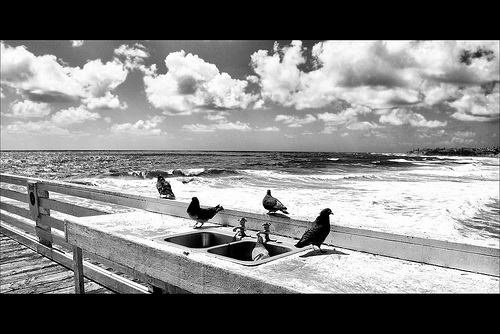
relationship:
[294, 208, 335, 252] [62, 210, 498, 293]
bird on counter area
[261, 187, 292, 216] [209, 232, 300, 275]
bird in sink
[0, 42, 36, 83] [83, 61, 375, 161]
clouds against sky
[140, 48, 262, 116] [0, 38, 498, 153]
cloud against sky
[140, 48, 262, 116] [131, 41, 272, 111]
cloud against sky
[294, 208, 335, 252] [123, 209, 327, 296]
bird on table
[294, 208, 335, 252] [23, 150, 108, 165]
bird outside by water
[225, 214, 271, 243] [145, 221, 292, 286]
faucet on double sink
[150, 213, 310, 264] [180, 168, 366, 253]
double sink near birds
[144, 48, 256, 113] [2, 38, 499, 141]
cloud in sky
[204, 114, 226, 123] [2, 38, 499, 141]
cloud in sky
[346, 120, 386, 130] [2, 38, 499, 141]
cloud in sky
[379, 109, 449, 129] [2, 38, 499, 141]
cloud in sky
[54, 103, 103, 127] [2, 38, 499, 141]
cloud in sky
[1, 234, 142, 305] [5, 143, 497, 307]
deck outside by water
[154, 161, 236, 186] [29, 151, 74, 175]
wave in water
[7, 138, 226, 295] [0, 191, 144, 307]
fence area by deck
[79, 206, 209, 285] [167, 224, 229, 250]
counter area near sink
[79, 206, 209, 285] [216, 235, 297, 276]
counter area near sink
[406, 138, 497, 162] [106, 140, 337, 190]
buildings behind water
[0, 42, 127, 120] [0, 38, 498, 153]
clouds in sky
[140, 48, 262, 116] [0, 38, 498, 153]
cloud in sky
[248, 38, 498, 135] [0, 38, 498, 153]
clouds in sky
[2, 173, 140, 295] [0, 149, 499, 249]
boardwalk near ocean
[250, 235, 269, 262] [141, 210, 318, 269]
bird in sink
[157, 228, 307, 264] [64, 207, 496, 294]
sink in wood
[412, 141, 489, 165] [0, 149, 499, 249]
rocky area near ocean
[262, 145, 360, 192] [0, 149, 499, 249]
waves coming in from ocean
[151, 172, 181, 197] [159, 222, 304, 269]
bird by an outdoor sink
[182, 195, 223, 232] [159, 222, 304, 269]
bird by an outdoor sink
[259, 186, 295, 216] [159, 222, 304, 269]
bird by an outdoor sink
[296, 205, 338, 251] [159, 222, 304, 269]
bird by an outdoor sink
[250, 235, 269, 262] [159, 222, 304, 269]
bird by an outdoor sink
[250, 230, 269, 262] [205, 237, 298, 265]
bird in right half of sink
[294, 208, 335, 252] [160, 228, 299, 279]
bird in sink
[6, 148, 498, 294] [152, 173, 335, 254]
water in front of where birds